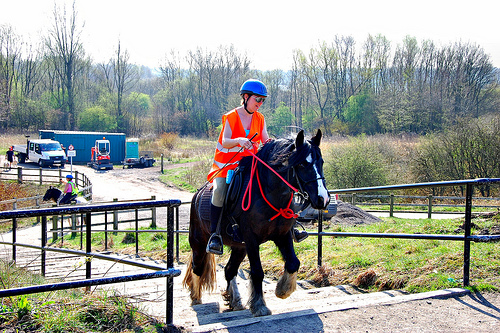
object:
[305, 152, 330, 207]
patch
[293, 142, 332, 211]
face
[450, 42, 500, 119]
tree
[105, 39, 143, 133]
tree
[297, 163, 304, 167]
yellow eye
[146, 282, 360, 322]
stairs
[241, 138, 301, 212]
reigns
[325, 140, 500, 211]
ground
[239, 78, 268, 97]
helmet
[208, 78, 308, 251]
person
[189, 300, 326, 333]
shadow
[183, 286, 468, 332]
steps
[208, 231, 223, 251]
shoe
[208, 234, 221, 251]
foot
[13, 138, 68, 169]
white truck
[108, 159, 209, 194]
dirt road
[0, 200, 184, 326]
fence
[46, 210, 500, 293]
fenced area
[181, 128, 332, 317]
horse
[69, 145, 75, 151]
sign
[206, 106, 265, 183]
construction jacket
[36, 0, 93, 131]
tree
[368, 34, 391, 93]
tree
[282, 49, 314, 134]
tree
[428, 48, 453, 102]
tree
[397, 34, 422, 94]
tree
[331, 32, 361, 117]
tree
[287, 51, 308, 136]
tree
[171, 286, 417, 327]
staircase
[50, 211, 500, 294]
grass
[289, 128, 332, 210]
head